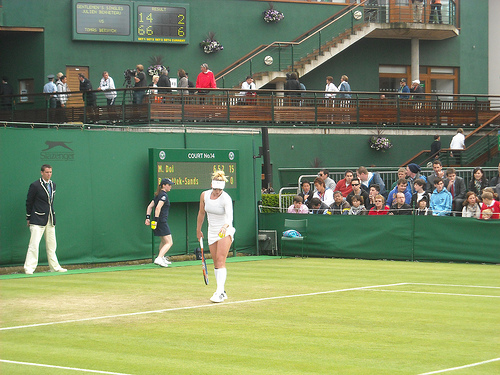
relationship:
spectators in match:
[278, 160, 499, 220] [25, 148, 387, 368]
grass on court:
[3, 253, 498, 374] [11, 252, 484, 373]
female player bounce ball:
[196, 170, 236, 303] [219, 232, 226, 238]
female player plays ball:
[196, 170, 236, 303] [219, 232, 226, 238]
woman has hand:
[317, 72, 337, 105] [214, 226, 226, 239]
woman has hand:
[467, 167, 489, 192] [195, 230, 205, 240]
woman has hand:
[365, 194, 390, 212] [446, 177, 457, 187]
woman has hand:
[143, 176, 177, 266] [480, 208, 492, 217]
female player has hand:
[196, 170, 236, 303] [142, 217, 152, 227]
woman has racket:
[317, 72, 337, 105] [198, 232, 209, 286]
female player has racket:
[196, 170, 236, 303] [201, 253, 209, 286]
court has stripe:
[11, 252, 484, 373] [367, 280, 498, 313]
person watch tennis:
[428, 175, 451, 216] [77, 144, 374, 364]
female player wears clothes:
[196, 170, 236, 303] [198, 189, 236, 243]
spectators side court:
[287, 160, 500, 220] [0, 252, 500, 375]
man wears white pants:
[17, 156, 87, 296] [20, 215, 70, 276]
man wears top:
[192, 62, 219, 106] [192, 64, 218, 89]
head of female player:
[205, 171, 232, 211] [196, 170, 236, 303]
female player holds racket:
[196, 170, 236, 303] [188, 226, 212, 291]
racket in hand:
[188, 226, 212, 291] [197, 231, 204, 242]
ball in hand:
[217, 232, 224, 239] [216, 230, 229, 241]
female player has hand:
[196, 170, 236, 303] [216, 230, 229, 241]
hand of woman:
[194, 224, 207, 249] [173, 150, 245, 302]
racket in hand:
[198, 232, 209, 286] [194, 224, 207, 249]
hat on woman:
[141, 183, 199, 204] [124, 177, 199, 257]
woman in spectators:
[368, 194, 391, 215] [287, 160, 500, 220]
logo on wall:
[39, 136, 80, 169] [3, 112, 483, 268]